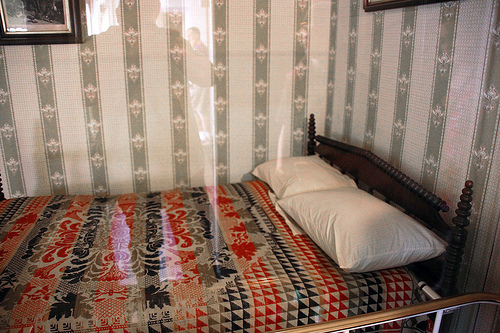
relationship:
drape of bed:
[0, 2, 498, 329] [4, 126, 474, 331]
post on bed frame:
[303, 113, 319, 155] [296, 104, 486, 284]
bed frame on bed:
[306, 113, 473, 333] [4, 126, 474, 331]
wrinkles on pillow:
[280, 201, 442, 268] [273, 184, 447, 273]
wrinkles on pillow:
[280, 201, 442, 268] [247, 152, 360, 199]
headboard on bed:
[305, 113, 471, 331] [0, 180, 422, 331]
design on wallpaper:
[0, 0, 500, 333] [0, 2, 338, 194]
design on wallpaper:
[0, 5, 495, 323] [14, 23, 326, 190]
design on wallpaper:
[0, 0, 500, 333] [1, 1, 499, 325]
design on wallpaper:
[0, 0, 500, 333] [2, 3, 494, 180]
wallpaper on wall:
[119, 40, 247, 158] [25, 113, 261, 172]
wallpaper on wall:
[317, 0, 497, 325] [308, 0, 495, 330]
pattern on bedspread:
[1, 190, 271, 331] [0, 177, 430, 331]